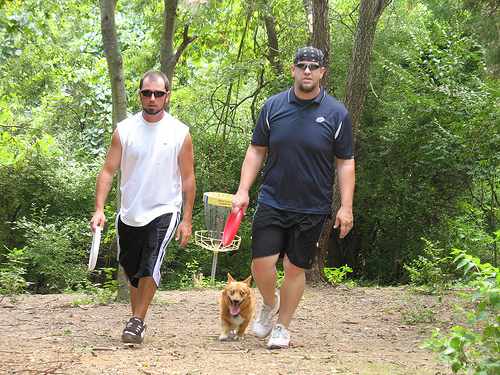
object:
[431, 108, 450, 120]
sky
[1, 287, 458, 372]
gravel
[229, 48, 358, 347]
guy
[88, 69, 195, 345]
guy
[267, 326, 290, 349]
shoe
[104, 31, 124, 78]
woods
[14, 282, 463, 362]
path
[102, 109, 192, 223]
shirt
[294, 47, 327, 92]
head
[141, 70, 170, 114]
head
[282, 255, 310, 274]
knee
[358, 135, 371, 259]
woods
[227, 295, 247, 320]
mouth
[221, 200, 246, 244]
disc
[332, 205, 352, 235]
hand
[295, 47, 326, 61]
bandanna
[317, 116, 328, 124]
logo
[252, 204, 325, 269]
shorts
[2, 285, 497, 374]
trail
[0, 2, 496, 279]
forest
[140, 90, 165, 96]
sunglasses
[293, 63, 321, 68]
sunglasses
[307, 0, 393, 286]
tree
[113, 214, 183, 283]
shorts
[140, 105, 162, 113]
beard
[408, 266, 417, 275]
leaves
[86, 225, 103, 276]
frisbee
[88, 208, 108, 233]
hand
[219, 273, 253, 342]
dog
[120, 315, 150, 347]
shoe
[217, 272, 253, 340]
corgi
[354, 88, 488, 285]
woods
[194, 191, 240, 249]
frisbee net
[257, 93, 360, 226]
shirt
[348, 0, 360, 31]
branch